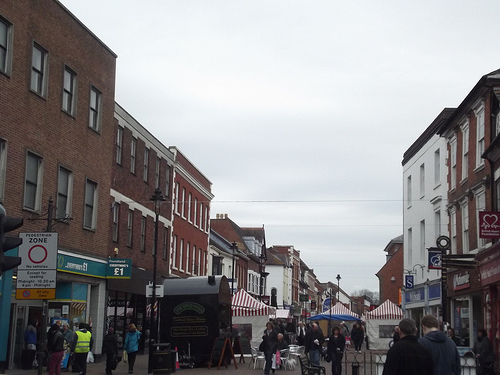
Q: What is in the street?
A: Tents.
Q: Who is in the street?
A: Pedestrians.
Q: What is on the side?
A: Buildings.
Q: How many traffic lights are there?
A: One.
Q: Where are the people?
A: In the road.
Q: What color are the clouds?
A: White.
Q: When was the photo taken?
A: During the day.